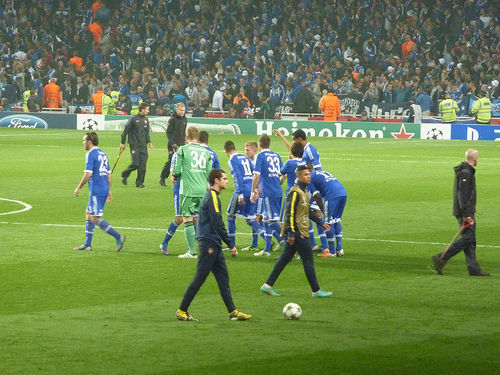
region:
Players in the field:
[80, 82, 417, 289]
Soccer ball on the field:
[163, 124, 347, 342]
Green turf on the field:
[71, 249, 197, 349]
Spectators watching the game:
[205, 65, 367, 138]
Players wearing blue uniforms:
[215, 123, 365, 232]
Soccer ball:
[261, 285, 363, 335]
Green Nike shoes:
[261, 277, 358, 309]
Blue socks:
[61, 204, 170, 304]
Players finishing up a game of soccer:
[68, 117, 415, 307]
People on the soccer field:
[96, 106, 418, 306]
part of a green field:
[397, 256, 450, 325]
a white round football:
[285, 305, 303, 317]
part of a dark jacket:
[196, 215, 215, 236]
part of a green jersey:
[186, 145, 203, 180]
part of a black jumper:
[443, 172, 466, 202]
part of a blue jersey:
[85, 152, 110, 188]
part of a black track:
[129, 148, 143, 170]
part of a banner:
[363, 120, 410, 145]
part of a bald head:
[458, 147, 476, 159]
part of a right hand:
[118, 137, 125, 154]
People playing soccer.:
[50, 37, 459, 364]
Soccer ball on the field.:
[271, 260, 342, 321]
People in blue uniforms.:
[197, 113, 428, 315]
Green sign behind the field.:
[230, 90, 477, 170]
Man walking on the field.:
[69, 111, 142, 288]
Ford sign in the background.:
[10, 110, 71, 160]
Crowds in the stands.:
[225, 47, 462, 124]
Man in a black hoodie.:
[422, 139, 495, 299]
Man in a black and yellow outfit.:
[166, 140, 320, 369]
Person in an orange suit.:
[295, 72, 372, 149]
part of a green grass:
[406, 325, 471, 361]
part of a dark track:
[206, 265, 226, 290]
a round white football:
[286, 305, 306, 319]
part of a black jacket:
[447, 180, 474, 206]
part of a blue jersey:
[323, 177, 339, 188]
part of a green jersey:
[182, 165, 201, 192]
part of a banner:
[340, 120, 418, 138]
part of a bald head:
[465, 145, 470, 163]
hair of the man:
[206, 167, 218, 177]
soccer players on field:
[78, 98, 430, 266]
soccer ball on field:
[253, 285, 325, 327]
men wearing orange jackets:
[29, 8, 113, 121]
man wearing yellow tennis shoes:
[166, 288, 266, 339]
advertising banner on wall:
[250, 118, 444, 140]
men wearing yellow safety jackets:
[431, 89, 499, 123]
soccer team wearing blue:
[217, 133, 346, 242]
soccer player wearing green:
[166, 126, 221, 256]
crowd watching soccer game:
[106, 1, 485, 118]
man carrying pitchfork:
[420, 148, 486, 280]